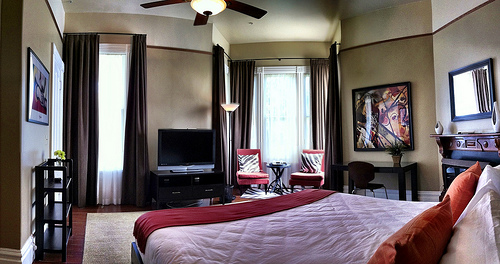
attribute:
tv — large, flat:
[160, 129, 217, 176]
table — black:
[153, 172, 226, 205]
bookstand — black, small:
[36, 159, 76, 262]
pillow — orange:
[367, 196, 454, 263]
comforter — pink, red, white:
[136, 189, 441, 263]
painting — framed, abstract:
[353, 80, 416, 149]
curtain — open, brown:
[63, 34, 149, 207]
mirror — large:
[450, 62, 496, 121]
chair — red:
[235, 147, 269, 191]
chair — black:
[349, 162, 390, 198]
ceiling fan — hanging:
[141, 1, 269, 26]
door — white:
[52, 44, 64, 225]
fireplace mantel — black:
[435, 134, 499, 203]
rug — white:
[84, 212, 160, 264]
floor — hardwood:
[34, 192, 297, 261]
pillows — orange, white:
[367, 162, 499, 263]